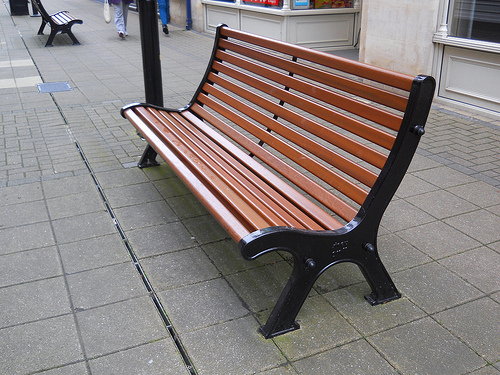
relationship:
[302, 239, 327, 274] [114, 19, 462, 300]
bolt on bench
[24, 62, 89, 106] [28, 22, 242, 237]
drain in sidewalk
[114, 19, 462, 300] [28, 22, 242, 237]
bench on sidewalk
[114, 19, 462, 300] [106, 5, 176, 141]
bench next to pole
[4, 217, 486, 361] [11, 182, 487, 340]
sidewalk with two benches